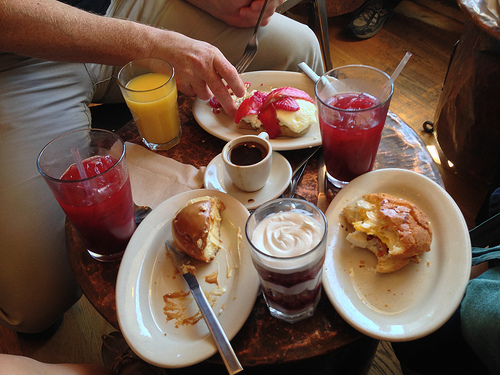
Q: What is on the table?
A: Plates and glasses.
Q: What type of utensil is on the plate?
A: Knife.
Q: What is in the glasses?
A: Beverages.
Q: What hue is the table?
A: Brown.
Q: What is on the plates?
A: Half eaten food.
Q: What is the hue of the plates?
A: White.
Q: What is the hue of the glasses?
A: Clear.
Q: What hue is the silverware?
A: Silver.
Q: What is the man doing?
A: Holding a fork.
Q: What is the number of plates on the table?
A: Three.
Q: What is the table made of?
A: Wood.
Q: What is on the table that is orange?
A: Orange juice.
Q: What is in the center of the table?
A: A coffee cup and saucer.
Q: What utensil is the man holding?
A: Fork.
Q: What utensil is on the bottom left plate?
A: Butter knife.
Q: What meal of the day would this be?
A: Breakfast.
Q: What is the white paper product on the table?
A: Napkin.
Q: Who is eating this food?
A: A man wearing tan pants.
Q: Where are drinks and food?
A: On a small table.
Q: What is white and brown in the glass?
A: Vanilla and chocolate milkshake.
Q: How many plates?
A: 4.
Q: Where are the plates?
A: The table.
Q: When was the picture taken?
A: Daytime.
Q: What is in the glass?
A: Juice.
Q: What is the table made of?
A: Wood.